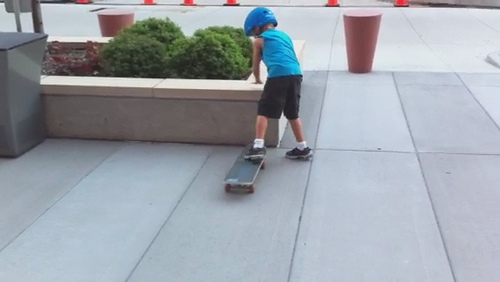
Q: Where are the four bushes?
A: In the concrete raised bed.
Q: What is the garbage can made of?
A: Gray metal.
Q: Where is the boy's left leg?
A: On the skateboard.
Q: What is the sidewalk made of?
A: Gray stone tiles.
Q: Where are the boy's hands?
A: Leaning on the raised bed.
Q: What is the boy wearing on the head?
A: Blue helmet.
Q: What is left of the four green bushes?
A: Dark green dirt.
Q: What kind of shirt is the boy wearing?
A: Blue sleeveless shirt.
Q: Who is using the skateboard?
A: A young man.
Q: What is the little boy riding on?
A: A skateboard.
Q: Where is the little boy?
A: Standing close to the planter box.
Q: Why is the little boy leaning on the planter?
A: To balance.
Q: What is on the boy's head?
A: A blue helmet.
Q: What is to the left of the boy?
A: A trash can.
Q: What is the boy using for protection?
A: A helmet.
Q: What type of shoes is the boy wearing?
A: Tennis shoes.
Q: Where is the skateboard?
A: Under the left foot of the small boy, dressed in blue.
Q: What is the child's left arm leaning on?
A: The edge of a cement planter with four, green shrubs in it.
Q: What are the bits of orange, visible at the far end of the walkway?
A: The bottom slivers of several, orange safety cones.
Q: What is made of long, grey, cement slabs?
A: The sidewalk.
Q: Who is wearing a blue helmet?
A: A child with one foot on a green skateboard.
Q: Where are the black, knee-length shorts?
A: On the boy with the skateboard.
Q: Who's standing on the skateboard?
A: Young child.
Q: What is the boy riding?
A: Skateboard.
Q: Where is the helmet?
A: On the boy's head.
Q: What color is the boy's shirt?
A: Blue.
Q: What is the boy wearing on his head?
A: Helmet.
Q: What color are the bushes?
A: Green.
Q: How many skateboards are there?
A: 1.